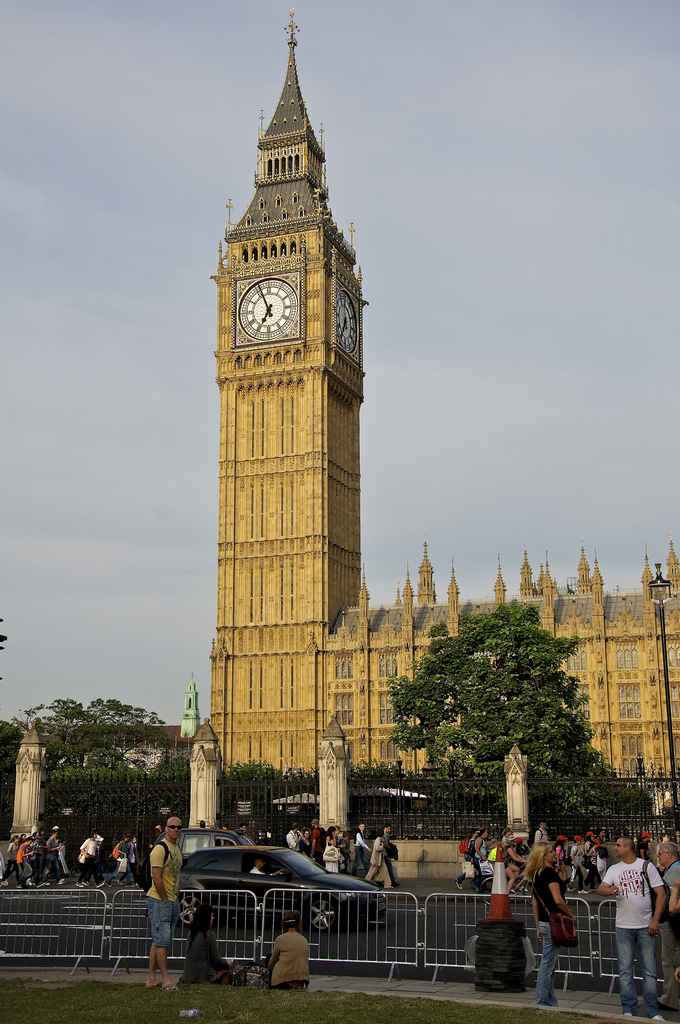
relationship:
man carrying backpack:
[139, 809, 196, 992] [136, 841, 173, 883]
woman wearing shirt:
[521, 833, 582, 1010] [532, 866, 566, 921]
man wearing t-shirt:
[590, 829, 674, 1015] [605, 856, 666, 932]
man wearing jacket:
[260, 916, 315, 994] [272, 930, 309, 976]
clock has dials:
[232, 268, 310, 350] [247, 283, 293, 329]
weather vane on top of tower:
[280, 5, 303, 42] [211, 7, 368, 632]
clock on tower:
[232, 268, 310, 350] [211, 7, 368, 632]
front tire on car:
[278, 899, 355, 928] [176, 842, 388, 939]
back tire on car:
[301, 890, 357, 954] [176, 842, 388, 939]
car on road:
[168, 828, 383, 941] [13, 883, 668, 967]